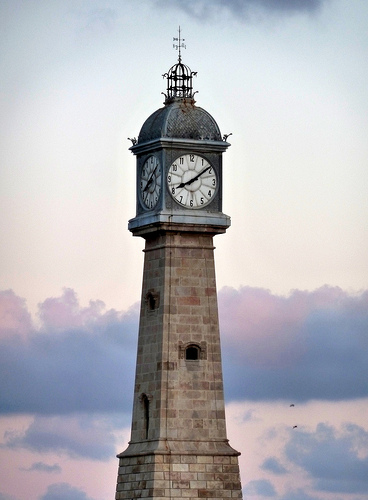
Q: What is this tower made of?
A: Bricks.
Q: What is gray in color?
A: Numbers on the clock.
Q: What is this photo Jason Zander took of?
A: Clock tower.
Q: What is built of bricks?
A: Tower clock base.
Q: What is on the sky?
A: Grey clouds.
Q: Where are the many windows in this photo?
A: On the brick tower.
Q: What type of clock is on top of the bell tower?
A: A numerical clock.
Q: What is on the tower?
A: Clock.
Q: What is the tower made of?
A: Brick.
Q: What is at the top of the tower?
A: Weather vane.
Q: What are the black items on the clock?
A: Hands.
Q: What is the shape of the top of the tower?
A: Dome.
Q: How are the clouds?
A: Colorful.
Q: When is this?
A: Daytime.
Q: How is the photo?
A: Clear.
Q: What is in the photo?
A: Clock.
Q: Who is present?
A: No one.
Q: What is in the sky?
A: Clouds.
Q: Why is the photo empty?
A: There is nobody.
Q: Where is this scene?
A: In the sky.